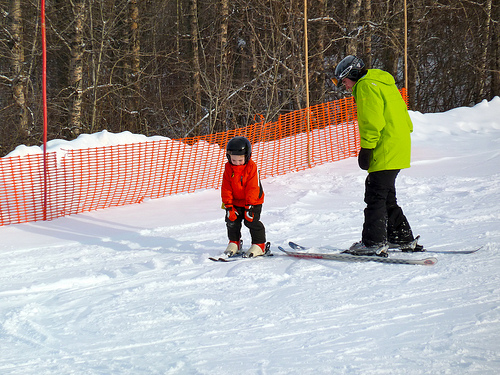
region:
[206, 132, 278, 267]
a child on a pair of skies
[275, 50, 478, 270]
a person on a pair of skies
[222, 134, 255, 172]
a helmet on the head of a child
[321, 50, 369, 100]
a helmet on the head of a person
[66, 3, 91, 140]
a trunk of a tree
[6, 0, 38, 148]
a trunk of a tree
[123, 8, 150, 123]
a trunk of a tree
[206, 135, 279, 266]
a child wearing an orange winter coat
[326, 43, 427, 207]
a person wearing a lime green winter coat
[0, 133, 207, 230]
an orange caution fence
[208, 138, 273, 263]
a kid standing on skis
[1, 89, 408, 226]
an orange fence in the snow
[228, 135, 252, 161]
kid wearing a black helmet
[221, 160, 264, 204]
kid wearing an orange winter coat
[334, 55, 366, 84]
man wearing a black helmet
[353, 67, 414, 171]
man wearing a lime green winter coat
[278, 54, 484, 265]
a man standing on skis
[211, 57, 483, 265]
a man and a kid wearing skis on the snow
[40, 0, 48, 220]
an orange pole sticking in the snow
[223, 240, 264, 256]
white and orange ski boots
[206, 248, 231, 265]
the ski on the ski slope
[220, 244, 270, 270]
the ski on the ski slope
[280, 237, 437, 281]
the ski on the ski slope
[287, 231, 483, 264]
the ski on the ski slope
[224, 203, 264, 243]
the black ski pants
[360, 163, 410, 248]
the black ski pants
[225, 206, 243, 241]
the leg of the skiier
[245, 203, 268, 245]
the leg of the skiier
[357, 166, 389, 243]
the leg of the skiier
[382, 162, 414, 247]
the leg of the skiier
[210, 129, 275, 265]
a little kid learning how to ski.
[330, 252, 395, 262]
ski sled on the ground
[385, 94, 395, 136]
man wearing a green jacket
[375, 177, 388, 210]
man has on black pants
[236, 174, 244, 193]
boy wearing red jacket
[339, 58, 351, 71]
man has on helmet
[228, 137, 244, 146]
boy has on a helmet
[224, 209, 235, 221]
boy wearing red and black gloves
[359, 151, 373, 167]
man has on black gloves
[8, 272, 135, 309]
prints in the snow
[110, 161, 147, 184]
orange net fence up